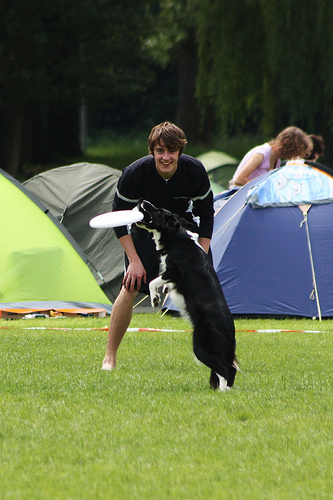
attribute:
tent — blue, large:
[187, 158, 331, 319]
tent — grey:
[18, 158, 174, 324]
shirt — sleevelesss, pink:
[228, 141, 280, 188]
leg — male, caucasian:
[98, 286, 140, 372]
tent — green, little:
[2, 169, 132, 338]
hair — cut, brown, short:
[142, 119, 188, 150]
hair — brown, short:
[147, 120, 186, 156]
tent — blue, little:
[155, 159, 332, 320]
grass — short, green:
[1, 131, 331, 498]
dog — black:
[126, 200, 249, 396]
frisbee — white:
[85, 205, 151, 232]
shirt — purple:
[227, 138, 286, 193]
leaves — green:
[193, 10, 319, 122]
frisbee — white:
[87, 203, 148, 236]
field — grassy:
[1, 300, 321, 490]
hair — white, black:
[142, 203, 238, 382]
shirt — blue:
[111, 152, 214, 239]